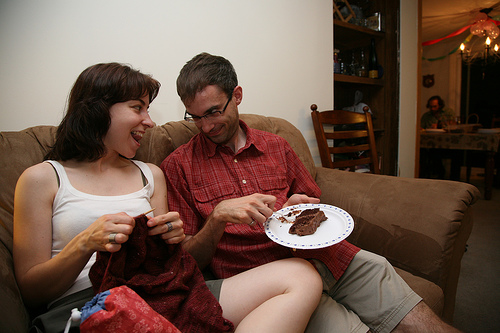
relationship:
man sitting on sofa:
[161, 52, 462, 331] [3, 114, 479, 330]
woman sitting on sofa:
[14, 63, 323, 329] [3, 114, 479, 330]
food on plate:
[289, 208, 329, 237] [264, 203, 355, 250]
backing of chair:
[310, 103, 379, 169] [309, 100, 434, 219]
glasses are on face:
[182, 109, 228, 122] [187, 91, 238, 142]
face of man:
[187, 91, 238, 142] [161, 52, 462, 331]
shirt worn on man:
[160, 123, 361, 291] [161, 52, 462, 331]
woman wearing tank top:
[14, 63, 323, 329] [38, 159, 152, 279]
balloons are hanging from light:
[469, 12, 496, 41] [455, 35, 500, 71]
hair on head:
[53, 64, 113, 166] [90, 63, 156, 159]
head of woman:
[90, 63, 156, 159] [14, 63, 323, 329]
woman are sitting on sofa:
[14, 63, 323, 333] [3, 114, 479, 330]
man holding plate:
[161, 52, 462, 331] [264, 203, 355, 250]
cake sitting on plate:
[298, 216, 314, 233] [264, 203, 355, 250]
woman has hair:
[14, 63, 323, 329] [53, 64, 113, 166]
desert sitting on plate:
[298, 216, 314, 233] [264, 203, 355, 250]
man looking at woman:
[161, 52, 462, 331] [14, 63, 323, 329]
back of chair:
[310, 103, 379, 169] [309, 100, 434, 219]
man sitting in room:
[424, 97, 459, 133] [422, 1, 496, 197]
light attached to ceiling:
[455, 35, 500, 71] [422, 2, 499, 29]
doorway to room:
[413, 6, 428, 188] [422, 1, 496, 197]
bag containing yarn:
[67, 285, 183, 332] [97, 244, 112, 293]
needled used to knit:
[125, 203, 156, 219] [90, 209, 188, 256]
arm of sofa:
[317, 162, 479, 276] [3, 114, 479, 330]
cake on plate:
[298, 216, 314, 233] [264, 203, 355, 250]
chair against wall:
[309, 100, 434, 219] [2, 0, 336, 164]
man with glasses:
[161, 52, 462, 331] [182, 109, 228, 122]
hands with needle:
[94, 211, 187, 254] [79, 203, 157, 252]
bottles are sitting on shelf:
[355, 38, 375, 79] [336, 1, 400, 176]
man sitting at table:
[424, 97, 459, 133] [420, 127, 500, 194]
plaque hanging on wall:
[424, 72, 436, 89] [423, 35, 463, 129]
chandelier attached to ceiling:
[455, 35, 500, 71] [422, 2, 499, 29]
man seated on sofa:
[161, 52, 462, 331] [3, 114, 479, 330]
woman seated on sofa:
[14, 63, 323, 329] [3, 114, 479, 330]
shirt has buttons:
[160, 123, 361, 291] [231, 155, 248, 189]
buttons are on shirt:
[231, 155, 248, 189] [160, 123, 361, 291]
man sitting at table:
[161, 52, 462, 331] [420, 127, 500, 194]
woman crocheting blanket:
[14, 63, 323, 329] [91, 219, 234, 332]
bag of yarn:
[67, 285, 183, 332] [97, 244, 112, 293]